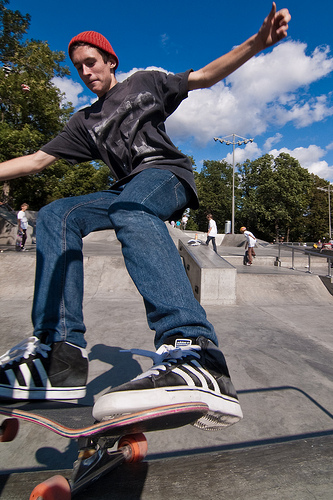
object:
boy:
[237, 223, 259, 269]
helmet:
[237, 222, 249, 231]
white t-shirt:
[205, 218, 215, 238]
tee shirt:
[37, 68, 200, 211]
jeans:
[29, 174, 223, 353]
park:
[0, 218, 331, 498]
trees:
[235, 137, 307, 234]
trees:
[197, 150, 255, 213]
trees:
[0, 0, 79, 246]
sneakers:
[89, 321, 242, 432]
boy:
[0, 2, 291, 432]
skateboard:
[0, 395, 208, 499]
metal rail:
[279, 239, 330, 261]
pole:
[289, 245, 298, 268]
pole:
[304, 254, 314, 274]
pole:
[324, 257, 332, 281]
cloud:
[165, 40, 332, 143]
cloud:
[260, 132, 282, 150]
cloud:
[264, 144, 332, 181]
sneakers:
[0, 330, 90, 409]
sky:
[2, 3, 331, 205]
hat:
[67, 30, 118, 71]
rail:
[271, 241, 331, 278]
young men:
[200, 208, 219, 257]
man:
[202, 212, 219, 251]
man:
[16, 199, 29, 253]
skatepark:
[0, 218, 331, 497]